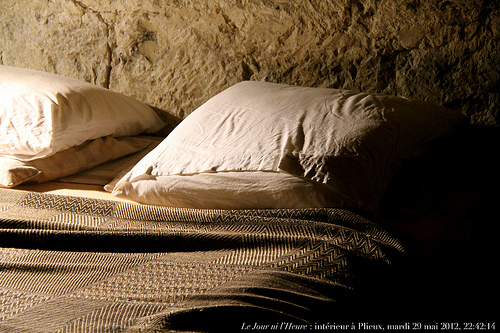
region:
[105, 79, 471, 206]
Most visible white pillow.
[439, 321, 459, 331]
White year 2012.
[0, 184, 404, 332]
Brown blanket on a bed.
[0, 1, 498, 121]
Brown stone wall behind pillows.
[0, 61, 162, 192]
Two less visible pillows stacked on top of each other.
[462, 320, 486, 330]
22:42 in white.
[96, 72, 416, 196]
white bed pillow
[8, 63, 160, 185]
two cotton white bed pillows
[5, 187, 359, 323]
woven mushroom colored bed blanket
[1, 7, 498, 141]
grey rock wall behind bed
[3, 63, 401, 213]
four crumpled cotton pillows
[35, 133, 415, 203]
cream colored cotton bed sheets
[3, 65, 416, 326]
bed made with all natural fiber bed linens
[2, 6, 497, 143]
brown rock wall behind pillows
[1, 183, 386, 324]
brown checked blanket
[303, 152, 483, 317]
dark space next to bed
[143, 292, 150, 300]
a dot on the blanket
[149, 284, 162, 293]
a dot on the blanket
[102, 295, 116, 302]
a dot on the blanket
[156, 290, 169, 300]
a dot on the blanket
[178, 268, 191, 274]
a dot on the blanket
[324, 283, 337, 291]
a dot on the blanket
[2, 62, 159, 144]
A white pillow on a bed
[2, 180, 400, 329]
A brown blanket on a bed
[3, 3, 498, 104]
A stone wall behind a bed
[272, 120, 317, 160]
A wrinkle in a pillow case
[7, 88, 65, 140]
Light shining on a pillow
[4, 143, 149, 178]
A flattened pillow under a fat pillow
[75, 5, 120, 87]
A crack in a stone wall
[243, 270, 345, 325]
Wrinkles on the blanket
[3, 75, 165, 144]
pillow on the left side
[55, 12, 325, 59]
stone wall behind bed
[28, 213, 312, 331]
knitted grey blanket on bed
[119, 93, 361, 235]
two pillow on the right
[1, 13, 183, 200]
two pillows on the left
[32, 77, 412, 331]
bed with pillows and blanket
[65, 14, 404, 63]
natural grey stone wall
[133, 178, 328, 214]
beige pillowcase on pillow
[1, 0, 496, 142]
rough surface of stone wall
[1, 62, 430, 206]
two stacks of two pillows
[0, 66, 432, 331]
pillows and blanket on bed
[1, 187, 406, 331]
blanket of unmade bed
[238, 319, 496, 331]
name and contact information of photographer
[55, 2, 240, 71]
bumpy textured brown wall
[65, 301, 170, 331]
diagonal pattern square of quilt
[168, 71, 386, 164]
cream colored pillow case with wrinkles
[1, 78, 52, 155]
light reflecting off surface of pillow case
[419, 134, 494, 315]
exceedingly dark patch of shadows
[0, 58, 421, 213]
two pillows at head of bed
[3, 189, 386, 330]
thin brown quilt with many patterns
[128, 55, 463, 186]
A pillow on a bed.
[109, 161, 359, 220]
A pillow on a bed.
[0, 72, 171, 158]
A pillow on a bed.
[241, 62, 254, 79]
A divot in the wall.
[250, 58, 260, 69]
A divot in the wall.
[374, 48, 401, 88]
A divot in the wall.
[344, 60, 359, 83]
A divot in the wall.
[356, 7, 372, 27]
A divot in the wall.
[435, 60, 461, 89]
A divot in the wall.